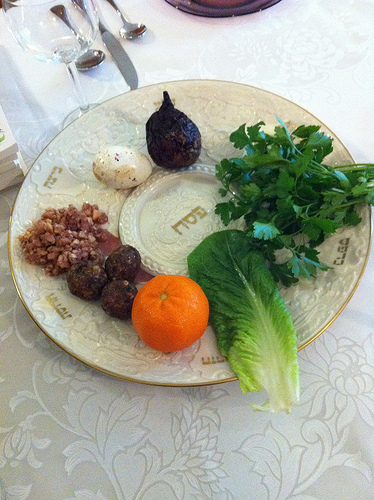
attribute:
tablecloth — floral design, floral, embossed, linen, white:
[1, 0, 371, 498]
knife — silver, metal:
[89, 0, 139, 92]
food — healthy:
[16, 89, 373, 415]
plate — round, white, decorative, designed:
[10, 76, 372, 387]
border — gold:
[7, 77, 372, 385]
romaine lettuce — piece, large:
[187, 228, 303, 413]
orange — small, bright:
[131, 274, 210, 355]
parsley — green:
[212, 114, 373, 288]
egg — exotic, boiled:
[92, 144, 152, 189]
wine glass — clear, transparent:
[1, 1, 100, 131]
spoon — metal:
[50, 3, 105, 70]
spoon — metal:
[106, 0, 147, 41]